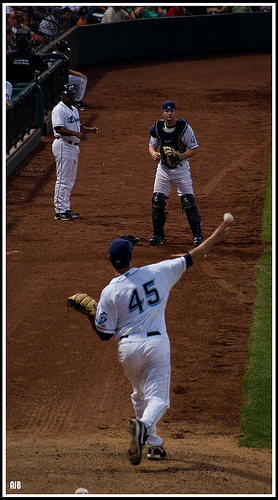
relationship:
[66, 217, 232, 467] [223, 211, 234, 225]
baseball player throwing ball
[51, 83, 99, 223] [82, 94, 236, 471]
baseball player watching players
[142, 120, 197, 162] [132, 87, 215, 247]
gear on catcher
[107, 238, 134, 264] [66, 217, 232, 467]
baseball hat on baseball player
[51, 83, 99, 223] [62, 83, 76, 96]
baseball player wearing helmet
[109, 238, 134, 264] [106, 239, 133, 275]
baseball hat on head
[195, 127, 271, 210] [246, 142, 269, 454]
marks beside grass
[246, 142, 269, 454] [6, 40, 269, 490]
grass in baseball feild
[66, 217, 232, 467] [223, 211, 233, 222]
baseball player throwing ball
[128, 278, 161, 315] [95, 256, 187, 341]
45 on baseball jersey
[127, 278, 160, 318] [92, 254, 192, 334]
print on jersey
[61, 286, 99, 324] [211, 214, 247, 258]
glove on hand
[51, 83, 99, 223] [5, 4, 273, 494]
baseball player on field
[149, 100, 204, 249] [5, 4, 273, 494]
catcher on field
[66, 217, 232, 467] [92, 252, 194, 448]
baseball player wearing uniform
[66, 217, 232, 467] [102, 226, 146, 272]
baseball player wearing cap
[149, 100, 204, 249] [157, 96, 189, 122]
catcher wearing cap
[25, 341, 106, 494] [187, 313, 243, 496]
ground covered in dirt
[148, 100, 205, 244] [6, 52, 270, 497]
catcher on field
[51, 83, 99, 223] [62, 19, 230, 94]
baseball player sitting near wall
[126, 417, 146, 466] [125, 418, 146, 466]
cleat on a foot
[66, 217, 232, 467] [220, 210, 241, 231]
baseball player pitching a ball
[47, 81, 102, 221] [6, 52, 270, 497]
baseball player standing on a field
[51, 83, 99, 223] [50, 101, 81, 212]
baseball player wearing a uniform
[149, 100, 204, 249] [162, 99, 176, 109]
catcher wearing a cap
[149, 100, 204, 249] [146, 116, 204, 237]
catcher wearing a uniform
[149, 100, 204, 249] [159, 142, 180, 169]
catcher wearing baseball glove